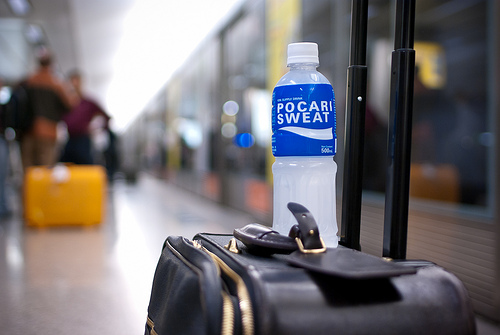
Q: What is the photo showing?
A: It is showing a train station.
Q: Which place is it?
A: It is a train station.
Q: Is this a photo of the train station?
A: Yes, it is showing the train station.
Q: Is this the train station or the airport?
A: It is the train station.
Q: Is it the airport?
A: No, it is the train station.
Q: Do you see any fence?
A: No, there are no fences.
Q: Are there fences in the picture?
A: No, there are no fences.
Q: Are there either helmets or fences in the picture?
A: No, there are no fences or helmets.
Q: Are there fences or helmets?
A: No, there are no fences or helmets.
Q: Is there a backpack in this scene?
A: Yes, there is a backpack.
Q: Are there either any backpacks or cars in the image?
A: Yes, there is a backpack.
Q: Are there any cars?
A: No, there are no cars.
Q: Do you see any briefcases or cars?
A: No, there are no cars or briefcases.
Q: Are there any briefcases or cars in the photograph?
A: No, there are no cars or briefcases.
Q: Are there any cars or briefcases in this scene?
A: No, there are no cars or briefcases.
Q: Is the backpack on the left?
A: Yes, the backpack is on the left of the image.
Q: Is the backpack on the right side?
A: No, the backpack is on the left of the image.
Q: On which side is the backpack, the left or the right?
A: The backpack is on the left of the image.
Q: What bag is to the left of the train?
A: The bag is a backpack.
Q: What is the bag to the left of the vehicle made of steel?
A: The bag is a backpack.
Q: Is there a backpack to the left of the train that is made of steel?
A: Yes, there is a backpack to the left of the train.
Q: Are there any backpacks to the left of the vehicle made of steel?
A: Yes, there is a backpack to the left of the train.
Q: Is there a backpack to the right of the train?
A: No, the backpack is to the left of the train.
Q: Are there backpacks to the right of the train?
A: No, the backpack is to the left of the train.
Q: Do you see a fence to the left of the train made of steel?
A: No, there is a backpack to the left of the train.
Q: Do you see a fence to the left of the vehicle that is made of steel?
A: No, there is a backpack to the left of the train.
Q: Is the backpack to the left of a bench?
A: No, the backpack is to the left of a train.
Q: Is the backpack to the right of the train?
A: No, the backpack is to the left of the train.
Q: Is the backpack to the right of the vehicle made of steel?
A: No, the backpack is to the left of the train.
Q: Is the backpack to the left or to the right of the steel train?
A: The backpack is to the left of the train.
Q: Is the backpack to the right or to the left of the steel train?
A: The backpack is to the left of the train.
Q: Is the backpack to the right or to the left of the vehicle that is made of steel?
A: The backpack is to the left of the train.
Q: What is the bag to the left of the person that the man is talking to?
A: The bag is a backpack.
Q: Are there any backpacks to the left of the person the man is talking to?
A: Yes, there is a backpack to the left of the person.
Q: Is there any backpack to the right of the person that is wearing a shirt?
A: No, the backpack is to the left of the person.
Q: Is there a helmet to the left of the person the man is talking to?
A: No, there is a backpack to the left of the person.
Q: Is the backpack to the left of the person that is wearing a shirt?
A: Yes, the backpack is to the left of the person.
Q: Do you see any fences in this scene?
A: No, there are no fences.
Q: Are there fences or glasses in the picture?
A: No, there are no fences or glasses.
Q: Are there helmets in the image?
A: No, there are no helmets.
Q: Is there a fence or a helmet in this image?
A: No, there are no helmets or fences.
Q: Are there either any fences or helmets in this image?
A: No, there are no helmets or fences.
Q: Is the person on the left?
A: Yes, the person is on the left of the image.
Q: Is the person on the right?
A: No, the person is on the left of the image.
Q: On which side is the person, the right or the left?
A: The person is on the left of the image.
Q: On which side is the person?
A: The person is on the left of the image.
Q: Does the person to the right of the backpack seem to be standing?
A: Yes, the person is standing.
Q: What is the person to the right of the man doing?
A: The person is standing.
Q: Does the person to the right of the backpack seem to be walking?
A: No, the person is standing.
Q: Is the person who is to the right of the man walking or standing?
A: The person is standing.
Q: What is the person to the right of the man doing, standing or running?
A: The person is standing.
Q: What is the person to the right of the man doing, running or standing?
A: The person is standing.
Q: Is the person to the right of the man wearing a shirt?
A: Yes, the person is wearing a shirt.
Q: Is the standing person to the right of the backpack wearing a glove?
A: No, the person is wearing a shirt.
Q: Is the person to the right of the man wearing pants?
A: Yes, the person is wearing pants.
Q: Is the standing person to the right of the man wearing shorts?
A: No, the person is wearing pants.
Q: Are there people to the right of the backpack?
A: Yes, there is a person to the right of the backpack.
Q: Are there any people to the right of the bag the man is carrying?
A: Yes, there is a person to the right of the backpack.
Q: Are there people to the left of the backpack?
A: No, the person is to the right of the backpack.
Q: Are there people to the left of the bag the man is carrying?
A: No, the person is to the right of the backpack.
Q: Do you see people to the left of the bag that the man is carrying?
A: No, the person is to the right of the backpack.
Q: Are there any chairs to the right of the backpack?
A: No, there is a person to the right of the backpack.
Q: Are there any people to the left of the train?
A: Yes, there is a person to the left of the train.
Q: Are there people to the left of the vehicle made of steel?
A: Yes, there is a person to the left of the train.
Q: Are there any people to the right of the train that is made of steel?
A: No, the person is to the left of the train.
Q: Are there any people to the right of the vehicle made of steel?
A: No, the person is to the left of the train.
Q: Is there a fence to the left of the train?
A: No, there is a person to the left of the train.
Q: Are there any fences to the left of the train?
A: No, there is a person to the left of the train.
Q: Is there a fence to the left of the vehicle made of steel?
A: No, there is a person to the left of the train.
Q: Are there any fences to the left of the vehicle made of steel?
A: No, there is a person to the left of the train.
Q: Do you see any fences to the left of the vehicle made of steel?
A: No, there is a person to the left of the train.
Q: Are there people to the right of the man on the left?
A: Yes, there is a person to the right of the man.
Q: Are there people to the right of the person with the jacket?
A: Yes, there is a person to the right of the man.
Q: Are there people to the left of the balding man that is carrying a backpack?
A: No, the person is to the right of the man.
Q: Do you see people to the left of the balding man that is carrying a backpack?
A: No, the person is to the right of the man.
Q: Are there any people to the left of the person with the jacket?
A: No, the person is to the right of the man.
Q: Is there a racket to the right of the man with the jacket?
A: No, there is a person to the right of the man.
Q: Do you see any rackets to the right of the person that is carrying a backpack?
A: No, there is a person to the right of the man.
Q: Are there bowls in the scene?
A: No, there are no bowls.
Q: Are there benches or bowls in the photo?
A: No, there are no bowls or benches.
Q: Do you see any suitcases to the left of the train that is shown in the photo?
A: Yes, there is a suitcase to the left of the train.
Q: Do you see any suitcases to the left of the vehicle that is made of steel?
A: Yes, there is a suitcase to the left of the train.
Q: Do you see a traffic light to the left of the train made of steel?
A: No, there is a suitcase to the left of the train.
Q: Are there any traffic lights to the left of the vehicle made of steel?
A: No, there is a suitcase to the left of the train.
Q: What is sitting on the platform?
A: The suitcase is sitting on the platform.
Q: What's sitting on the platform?
A: The suitcase is sitting on the platform.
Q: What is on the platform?
A: The suitcase is on the platform.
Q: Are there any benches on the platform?
A: No, there is a suitcase on the platform.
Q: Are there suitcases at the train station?
A: Yes, there is a suitcase at the train station.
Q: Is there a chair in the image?
A: No, there are no chairs.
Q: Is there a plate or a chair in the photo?
A: No, there are no chairs or plates.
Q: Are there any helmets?
A: No, there are no helmets.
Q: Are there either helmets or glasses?
A: No, there are no helmets or glasses.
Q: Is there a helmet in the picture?
A: No, there are no helmets.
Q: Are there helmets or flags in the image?
A: No, there are no helmets or flags.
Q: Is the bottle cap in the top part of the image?
A: Yes, the bottle cap is in the top of the image.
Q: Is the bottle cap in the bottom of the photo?
A: No, the bottle cap is in the top of the image.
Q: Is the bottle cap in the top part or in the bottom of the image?
A: The bottle cap is in the top of the image.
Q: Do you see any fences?
A: No, there are no fences.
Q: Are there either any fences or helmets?
A: No, there are no fences or helmets.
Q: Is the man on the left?
A: Yes, the man is on the left of the image.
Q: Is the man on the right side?
A: No, the man is on the left of the image.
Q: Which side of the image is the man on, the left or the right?
A: The man is on the left of the image.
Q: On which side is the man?
A: The man is on the left of the image.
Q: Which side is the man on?
A: The man is on the left of the image.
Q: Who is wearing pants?
A: The man is wearing pants.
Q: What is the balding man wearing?
A: The man is wearing trousers.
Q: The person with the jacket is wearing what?
A: The man is wearing trousers.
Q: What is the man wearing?
A: The man is wearing trousers.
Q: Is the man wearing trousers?
A: Yes, the man is wearing trousers.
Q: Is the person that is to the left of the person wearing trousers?
A: Yes, the man is wearing trousers.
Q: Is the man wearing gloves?
A: No, the man is wearing trousers.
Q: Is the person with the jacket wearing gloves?
A: No, the man is wearing trousers.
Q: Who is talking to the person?
A: The man is talking to the person.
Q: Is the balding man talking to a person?
A: Yes, the man is talking to a person.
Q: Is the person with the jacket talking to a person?
A: Yes, the man is talking to a person.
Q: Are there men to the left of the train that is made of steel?
A: Yes, there is a man to the left of the train.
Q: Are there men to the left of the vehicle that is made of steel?
A: Yes, there is a man to the left of the train.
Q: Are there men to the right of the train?
A: No, the man is to the left of the train.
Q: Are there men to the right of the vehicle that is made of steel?
A: No, the man is to the left of the train.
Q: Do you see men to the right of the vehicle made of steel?
A: No, the man is to the left of the train.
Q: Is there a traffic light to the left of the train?
A: No, there is a man to the left of the train.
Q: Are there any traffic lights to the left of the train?
A: No, there is a man to the left of the train.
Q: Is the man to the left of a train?
A: Yes, the man is to the left of a train.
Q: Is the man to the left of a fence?
A: No, the man is to the left of a train.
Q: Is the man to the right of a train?
A: No, the man is to the left of a train.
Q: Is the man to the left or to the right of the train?
A: The man is to the left of the train.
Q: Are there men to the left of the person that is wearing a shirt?
A: Yes, there is a man to the left of the person.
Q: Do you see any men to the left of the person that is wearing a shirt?
A: Yes, there is a man to the left of the person.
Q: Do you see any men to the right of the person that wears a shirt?
A: No, the man is to the left of the person.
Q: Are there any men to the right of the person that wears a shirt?
A: No, the man is to the left of the person.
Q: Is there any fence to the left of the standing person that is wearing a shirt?
A: No, there is a man to the left of the person.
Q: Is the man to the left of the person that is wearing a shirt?
A: Yes, the man is to the left of the person.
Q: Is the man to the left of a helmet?
A: No, the man is to the left of the person.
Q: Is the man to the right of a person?
A: No, the man is to the left of a person.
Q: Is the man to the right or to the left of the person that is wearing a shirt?
A: The man is to the left of the person.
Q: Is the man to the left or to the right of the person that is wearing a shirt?
A: The man is to the left of the person.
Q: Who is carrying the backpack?
A: The man is carrying the backpack.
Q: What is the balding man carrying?
A: The man is carrying a backpack.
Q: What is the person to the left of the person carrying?
A: The man is carrying a backpack.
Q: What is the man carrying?
A: The man is carrying a backpack.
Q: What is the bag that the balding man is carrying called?
A: The bag is a backpack.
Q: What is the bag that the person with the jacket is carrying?
A: The bag is a backpack.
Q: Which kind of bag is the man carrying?
A: The man is carrying a backpack.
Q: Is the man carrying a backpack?
A: Yes, the man is carrying a backpack.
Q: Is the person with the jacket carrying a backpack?
A: Yes, the man is carrying a backpack.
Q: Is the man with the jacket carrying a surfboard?
A: No, the man is carrying a backpack.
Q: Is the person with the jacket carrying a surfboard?
A: No, the man is carrying a backpack.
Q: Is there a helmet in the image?
A: No, there are no helmets.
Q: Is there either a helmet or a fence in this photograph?
A: No, there are no helmets or fences.